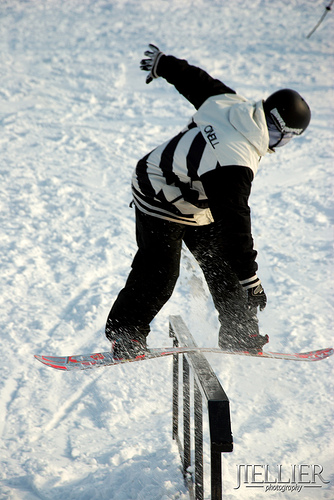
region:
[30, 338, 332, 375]
a snowboard under the person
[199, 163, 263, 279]
the arm of a person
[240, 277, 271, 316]
the hand of a person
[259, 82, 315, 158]
the head of a person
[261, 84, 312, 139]
a helmet on the person's head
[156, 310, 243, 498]
a black metal railing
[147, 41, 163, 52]
the finger of a person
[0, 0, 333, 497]
white snow on the ground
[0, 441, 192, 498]
a shadow on the ground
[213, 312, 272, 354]
a black snow boot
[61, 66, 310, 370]
snow boarder balancing on rail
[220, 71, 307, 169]
snow boarder with black helmet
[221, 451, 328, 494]
photographer label for photo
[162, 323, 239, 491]
black rail in snow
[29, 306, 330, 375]
red and gray snowboard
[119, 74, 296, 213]
snowboarder wearing black and white jacket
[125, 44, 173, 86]
black and white glove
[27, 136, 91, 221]
white snow on ground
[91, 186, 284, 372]
snowboarder wearing black pants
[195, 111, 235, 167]
name brand of jacket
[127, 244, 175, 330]
the pants are black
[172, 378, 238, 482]
the rail is mettalic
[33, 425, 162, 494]
the ground is covered in snow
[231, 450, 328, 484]
the photographer is jteller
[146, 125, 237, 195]
the jacket is white and black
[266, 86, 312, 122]
the helmet is black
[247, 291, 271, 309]
the gloves are black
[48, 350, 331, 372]
the skies are red and grey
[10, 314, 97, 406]
there are ski tracks on the snow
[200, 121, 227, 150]
onell wording is on the back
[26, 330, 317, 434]
the board is small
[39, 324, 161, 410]
the board is small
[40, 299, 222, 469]
the board is small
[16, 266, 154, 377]
the board is small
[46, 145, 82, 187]
White snow on ground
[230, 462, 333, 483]
Silver lettering on picture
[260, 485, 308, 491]
Word photography in small print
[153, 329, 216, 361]
Middle of snow board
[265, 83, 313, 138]
Man wearing black helmet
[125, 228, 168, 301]
Man wearing black pants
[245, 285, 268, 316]
Man wearing black gloves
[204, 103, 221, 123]
Man wearing white coat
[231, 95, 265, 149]
White hood on coat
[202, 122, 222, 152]
Black lettering on white coat